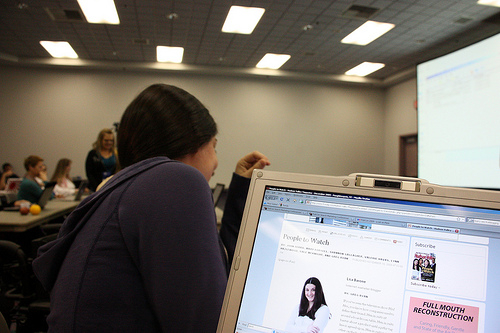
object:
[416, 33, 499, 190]
projector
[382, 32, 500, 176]
wall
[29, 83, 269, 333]
people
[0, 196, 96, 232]
desks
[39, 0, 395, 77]
lights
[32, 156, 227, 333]
hoodie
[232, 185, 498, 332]
screen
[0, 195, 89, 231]
table top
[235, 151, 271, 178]
hand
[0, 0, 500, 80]
tiles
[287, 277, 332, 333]
woman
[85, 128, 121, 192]
woman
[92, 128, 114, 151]
blonde hair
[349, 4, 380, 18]
vent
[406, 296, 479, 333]
advertisement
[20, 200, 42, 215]
fruit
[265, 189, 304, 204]
browser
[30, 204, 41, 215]
apple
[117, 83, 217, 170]
hair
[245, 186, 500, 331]
web page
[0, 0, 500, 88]
ceiling